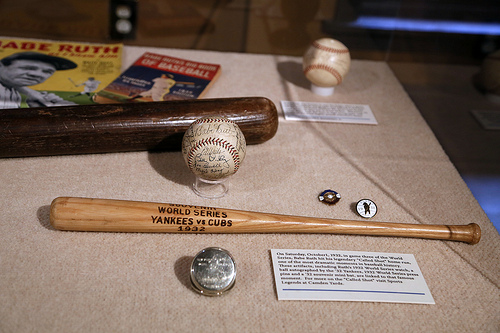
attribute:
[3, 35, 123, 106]
magazine — yellow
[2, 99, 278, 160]
baseball bat — wooden, dark brown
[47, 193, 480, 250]
baseball bat — wooden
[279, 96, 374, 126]
information card — white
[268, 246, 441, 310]
information card — white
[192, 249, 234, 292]
object — metal, shiny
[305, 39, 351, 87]
baseball — autographed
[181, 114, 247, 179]
baseball — autographed, signed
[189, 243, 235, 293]
coin — silver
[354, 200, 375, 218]
button — white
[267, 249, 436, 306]
card — small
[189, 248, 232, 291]
coin — silver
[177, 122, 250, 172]
baseball — old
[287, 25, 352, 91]
baseball — old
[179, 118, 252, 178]
baseball — white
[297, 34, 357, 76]
baseball — white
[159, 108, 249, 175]
baseball — round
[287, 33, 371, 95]
baseball — round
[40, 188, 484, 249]
bat — for baseball, wood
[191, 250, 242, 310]
item — round, silver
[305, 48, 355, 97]
ball — white, round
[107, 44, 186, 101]
book — baseball, old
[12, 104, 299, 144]
bat — dark, wood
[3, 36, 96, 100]
magazine — old, baseball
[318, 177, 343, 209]
pin — blue, white, gold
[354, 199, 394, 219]
pin — round, baseball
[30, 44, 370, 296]
memorabilia — baseball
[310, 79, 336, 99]
base — white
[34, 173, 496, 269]
bat — wood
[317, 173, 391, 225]
pins — small, round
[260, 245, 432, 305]
card — white, black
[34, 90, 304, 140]
bat — wood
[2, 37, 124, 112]
book — of baseball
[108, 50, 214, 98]
book — of baseball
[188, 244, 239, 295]
cover — round, silver, etched